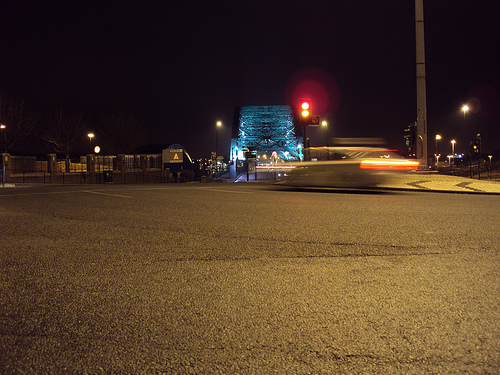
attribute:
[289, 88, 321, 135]
light — bright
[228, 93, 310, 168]
trusses — steel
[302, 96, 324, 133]
light — yellow, red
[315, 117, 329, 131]
light — bright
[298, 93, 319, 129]
light — bright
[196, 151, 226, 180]
buildings — tall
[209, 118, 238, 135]
light outside — bright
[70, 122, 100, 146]
light outside — bright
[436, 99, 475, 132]
light outside — bright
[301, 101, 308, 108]
light — bright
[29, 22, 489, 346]
scene — night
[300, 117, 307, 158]
oile — black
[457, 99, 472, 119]
light — street, lit, several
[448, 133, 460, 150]
light — street, lit, several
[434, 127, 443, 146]
light — street, lit, several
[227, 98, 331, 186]
bridge — blue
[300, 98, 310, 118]
light — bright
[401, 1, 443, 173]
pole — tall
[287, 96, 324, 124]
lights — red, orange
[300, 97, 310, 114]
light — bright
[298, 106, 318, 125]
light — bright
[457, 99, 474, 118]
light — bright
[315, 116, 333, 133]
light — bright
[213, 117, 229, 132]
light — bright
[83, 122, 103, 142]
light — bright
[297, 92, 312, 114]
light — bright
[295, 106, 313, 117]
light — bright